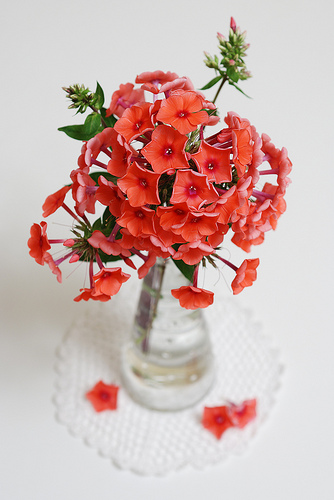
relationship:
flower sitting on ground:
[88, 379, 120, 413] [0, 258, 332, 496]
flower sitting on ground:
[199, 402, 237, 441] [0, 258, 332, 496]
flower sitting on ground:
[227, 397, 261, 429] [0, 258, 332, 496]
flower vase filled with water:
[122, 255, 215, 408] [121, 343, 216, 411]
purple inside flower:
[188, 184, 199, 195] [166, 166, 211, 211]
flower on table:
[88, 379, 120, 413] [0, 258, 332, 496]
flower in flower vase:
[168, 284, 215, 313] [122, 255, 215, 408]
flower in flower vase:
[229, 256, 261, 293] [122, 255, 215, 408]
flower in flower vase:
[90, 267, 133, 299] [122, 255, 215, 408]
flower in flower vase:
[27, 219, 53, 266] [122, 255, 215, 408]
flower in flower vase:
[166, 166, 211, 211] [122, 255, 215, 408]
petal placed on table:
[199, 402, 237, 441] [3, 199, 332, 499]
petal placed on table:
[227, 397, 261, 429] [3, 199, 332, 499]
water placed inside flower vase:
[121, 343, 216, 411] [122, 255, 215, 408]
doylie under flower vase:
[56, 298, 283, 476] [122, 255, 215, 408]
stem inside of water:
[138, 261, 166, 362] [121, 343, 216, 411]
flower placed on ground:
[88, 379, 120, 413] [0, 258, 332, 496]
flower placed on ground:
[199, 402, 237, 441] [0, 258, 332, 496]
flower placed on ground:
[227, 397, 261, 429] [0, 258, 332, 496]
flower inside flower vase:
[27, 219, 53, 266] [122, 255, 215, 408]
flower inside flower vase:
[90, 267, 133, 299] [122, 255, 215, 408]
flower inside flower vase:
[168, 284, 215, 313] [122, 255, 215, 408]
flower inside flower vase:
[229, 256, 261, 293] [122, 255, 215, 408]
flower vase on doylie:
[122, 255, 215, 408] [56, 298, 283, 476]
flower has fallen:
[199, 402, 237, 441] [198, 399, 238, 439]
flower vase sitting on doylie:
[122, 255, 215, 408] [56, 298, 283, 476]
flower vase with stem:
[122, 255, 215, 408] [138, 261, 166, 362]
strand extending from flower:
[212, 252, 237, 271] [229, 256, 261, 293]